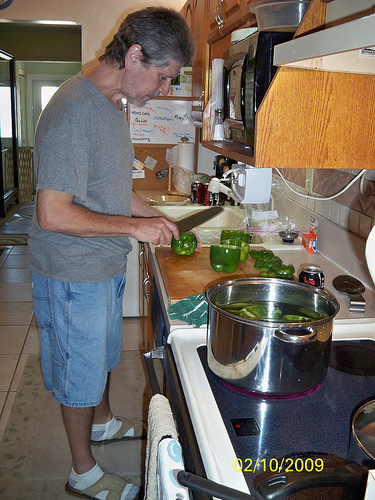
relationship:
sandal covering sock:
[67, 472, 135, 499] [69, 456, 140, 497]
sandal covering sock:
[92, 419, 154, 442] [89, 414, 132, 438]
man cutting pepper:
[21, 0, 201, 498] [169, 217, 205, 258]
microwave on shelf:
[217, 30, 295, 154] [187, 30, 354, 168]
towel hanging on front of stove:
[143, 394, 190, 498] [147, 321, 374, 498]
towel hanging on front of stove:
[153, 435, 189, 498] [147, 321, 374, 498]